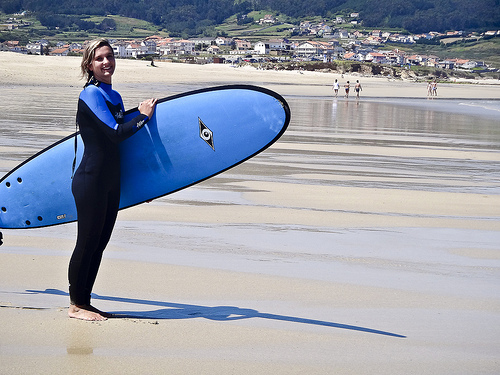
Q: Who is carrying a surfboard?
A: A woman.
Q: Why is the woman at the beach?
A: To surf.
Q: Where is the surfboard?
A: Under the woman's arm.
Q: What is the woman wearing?
A: Wetsuit.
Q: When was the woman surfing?
A: Daytime.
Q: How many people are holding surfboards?
A: One.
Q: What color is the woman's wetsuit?
A: Black and blue.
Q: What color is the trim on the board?
A: Black.